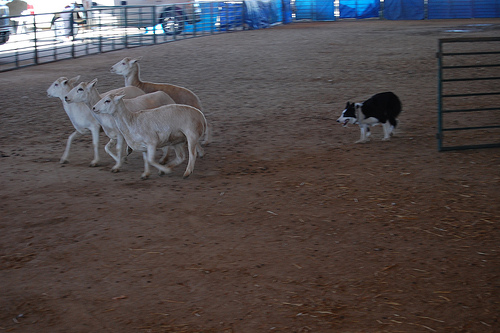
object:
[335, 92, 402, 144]
dog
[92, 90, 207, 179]
sheep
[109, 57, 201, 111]
sheep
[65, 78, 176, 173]
sheep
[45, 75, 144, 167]
sheep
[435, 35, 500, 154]
gate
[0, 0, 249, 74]
fence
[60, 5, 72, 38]
man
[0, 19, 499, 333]
ground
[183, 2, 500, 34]
tarp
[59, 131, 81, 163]
leg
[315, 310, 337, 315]
hay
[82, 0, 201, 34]
truck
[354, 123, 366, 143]
leg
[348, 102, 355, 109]
ear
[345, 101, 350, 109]
ear